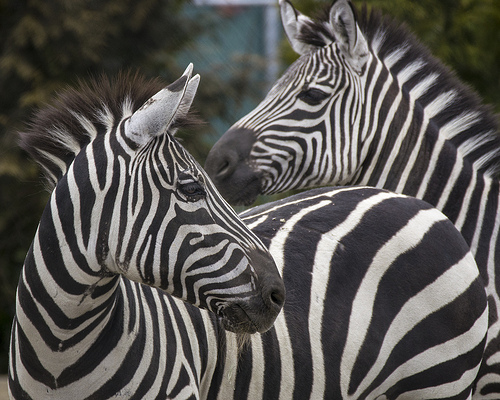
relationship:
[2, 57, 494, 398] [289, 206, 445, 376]
zebra has stripes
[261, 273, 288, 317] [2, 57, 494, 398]
black nose on zebra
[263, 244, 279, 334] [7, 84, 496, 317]
nose on zebra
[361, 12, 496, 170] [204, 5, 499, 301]
mane of zebra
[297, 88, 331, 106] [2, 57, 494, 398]
dark eye of zebra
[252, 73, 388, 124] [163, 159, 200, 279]
dark eye on zebra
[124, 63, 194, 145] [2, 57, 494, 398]
ears of zebra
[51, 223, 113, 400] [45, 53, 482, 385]
stripes on zebra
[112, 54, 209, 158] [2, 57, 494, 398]
ears of a zebra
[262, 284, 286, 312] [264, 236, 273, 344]
black nose of a zebra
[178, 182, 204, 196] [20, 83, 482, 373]
eye of a zebra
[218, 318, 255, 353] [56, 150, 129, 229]
whiskers on mouth of zebra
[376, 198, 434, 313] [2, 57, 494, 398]
hind end of zebra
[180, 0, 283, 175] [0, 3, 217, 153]
fence between trees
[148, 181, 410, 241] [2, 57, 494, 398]
back of a zebra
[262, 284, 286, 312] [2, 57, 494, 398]
black nose of a zebra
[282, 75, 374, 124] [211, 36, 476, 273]
eye of a zebra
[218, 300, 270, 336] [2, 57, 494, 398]
mouth of a zebra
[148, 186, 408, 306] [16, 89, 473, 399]
back of zebra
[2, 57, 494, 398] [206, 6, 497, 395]
zebra next to zebra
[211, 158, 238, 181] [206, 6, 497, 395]
nose on zebra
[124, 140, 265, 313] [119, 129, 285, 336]
stripes on face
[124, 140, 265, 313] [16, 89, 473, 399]
stripes on zebra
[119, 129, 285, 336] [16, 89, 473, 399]
face on zebra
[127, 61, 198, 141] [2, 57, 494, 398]
ears on zebra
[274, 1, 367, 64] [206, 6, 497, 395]
ears on zebra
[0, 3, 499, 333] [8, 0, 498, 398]
trees behind zebras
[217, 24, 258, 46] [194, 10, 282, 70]
wall of building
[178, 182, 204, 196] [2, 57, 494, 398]
eye of zebra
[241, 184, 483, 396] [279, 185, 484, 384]
stripes on zebra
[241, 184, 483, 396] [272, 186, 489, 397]
stripes on rump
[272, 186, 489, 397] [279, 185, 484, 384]
rump on zebra